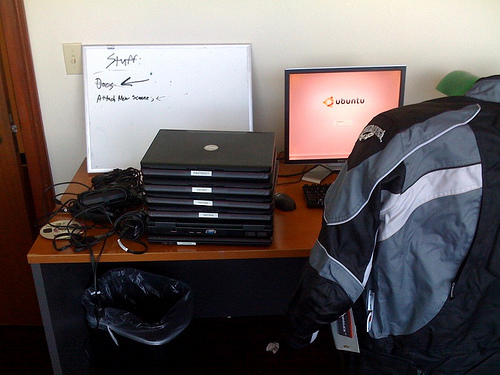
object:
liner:
[79, 266, 197, 333]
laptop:
[137, 155, 273, 179]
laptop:
[138, 183, 272, 204]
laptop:
[140, 204, 273, 223]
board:
[84, 44, 253, 174]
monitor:
[282, 66, 409, 165]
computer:
[330, 309, 362, 359]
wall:
[22, 0, 499, 203]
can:
[81, 266, 197, 348]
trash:
[261, 336, 282, 359]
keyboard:
[304, 182, 330, 210]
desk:
[26, 157, 341, 272]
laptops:
[141, 127, 279, 246]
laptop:
[144, 197, 270, 214]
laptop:
[141, 167, 275, 184]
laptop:
[143, 222, 274, 238]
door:
[0, 89, 35, 329]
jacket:
[278, 74, 498, 374]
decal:
[203, 143, 220, 152]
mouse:
[275, 191, 299, 214]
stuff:
[105, 52, 141, 72]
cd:
[39, 218, 84, 239]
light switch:
[62, 42, 83, 76]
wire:
[53, 218, 110, 268]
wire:
[93, 167, 137, 186]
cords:
[40, 166, 143, 264]